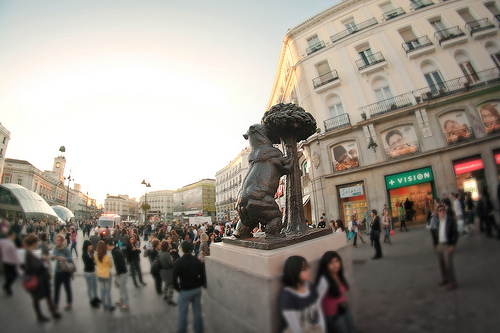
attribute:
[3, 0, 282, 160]
sky — blue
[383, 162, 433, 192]
sign — green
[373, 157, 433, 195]
light — neon, green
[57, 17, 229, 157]
clouds — white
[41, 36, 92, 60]
clouds — white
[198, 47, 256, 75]
clouds — white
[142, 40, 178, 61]
clouds — white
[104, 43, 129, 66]
clouds — white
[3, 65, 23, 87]
clouds — white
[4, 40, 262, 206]
cloud — white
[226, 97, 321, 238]
statue — brown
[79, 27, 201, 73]
cloud — white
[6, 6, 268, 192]
clouds — white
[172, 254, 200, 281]
sweater — black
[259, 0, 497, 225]
building — stone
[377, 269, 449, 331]
ground — cement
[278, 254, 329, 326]
woman — young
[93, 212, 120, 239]
truck — white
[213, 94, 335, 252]
statue — bronze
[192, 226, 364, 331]
platform — elevated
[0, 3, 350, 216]
sky — blue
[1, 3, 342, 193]
sky — blue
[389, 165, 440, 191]
light — green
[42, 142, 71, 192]
tower — stone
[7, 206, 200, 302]
crowd — people